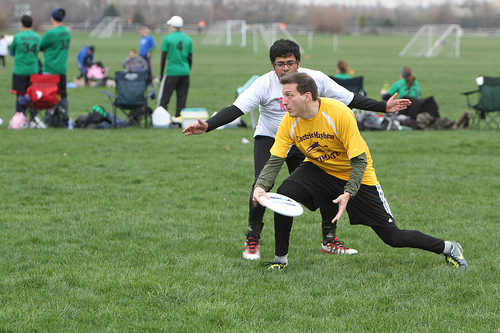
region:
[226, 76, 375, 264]
a man holding a frisbee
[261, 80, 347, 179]
a man wearing a yellow shirt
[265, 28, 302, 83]
a man wearing glasses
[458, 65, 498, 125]
a green folding chair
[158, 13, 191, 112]
a person wearing a green shirt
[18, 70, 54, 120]
a red folding chair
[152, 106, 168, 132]
a blue and white cooler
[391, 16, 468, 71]
a soccer goal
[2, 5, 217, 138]
people standing in a sports field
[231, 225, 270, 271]
a white and red tennis shoe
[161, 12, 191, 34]
white hat on a persons head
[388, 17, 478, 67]
soccer goal in a field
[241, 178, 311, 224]
frisbee in a persons hand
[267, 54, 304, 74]
glasses on a persons face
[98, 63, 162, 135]
blue chair on the ground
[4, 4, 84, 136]
two people with green shirts standing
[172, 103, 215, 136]
cooler on the ground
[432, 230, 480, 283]
shoe on a persons foot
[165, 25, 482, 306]
two people playing a game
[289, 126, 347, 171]
logo on a persons shirt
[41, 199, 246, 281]
green grass on field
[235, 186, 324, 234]
round white Frisbee in man's hand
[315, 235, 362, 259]
red laces on white sneakers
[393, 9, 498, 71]
white goal post on field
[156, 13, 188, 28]
white cap on man's head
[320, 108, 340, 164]
white stripe on yellow shirt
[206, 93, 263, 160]
portion of long sleeve black shirt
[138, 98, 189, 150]
white and blue cooler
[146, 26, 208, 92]
green shirt with number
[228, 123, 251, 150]
white paper on green grass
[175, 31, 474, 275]
two men playing frisbee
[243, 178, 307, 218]
Frisbee in man's hand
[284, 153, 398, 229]
black shorts with white stripes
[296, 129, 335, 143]
words on yellow shirt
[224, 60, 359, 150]
white short sleeved shirt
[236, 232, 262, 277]
sneaker with red shoe laces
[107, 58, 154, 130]
portable chair on field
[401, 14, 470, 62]
soccer nets on field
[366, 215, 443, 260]
black pants under shorts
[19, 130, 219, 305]
beautiful field of green grass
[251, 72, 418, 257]
man throwing a white frisbie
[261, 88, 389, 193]
man with yellow pullover on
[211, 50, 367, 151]
man wearing white shirt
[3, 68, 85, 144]
bright red lawn chair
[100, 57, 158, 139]
navy blue lawn chair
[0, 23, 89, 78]
two men wearing dark green jerseys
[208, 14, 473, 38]
soccer nets in the background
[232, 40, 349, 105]
man wearing black glasses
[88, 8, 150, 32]
two green pine trees